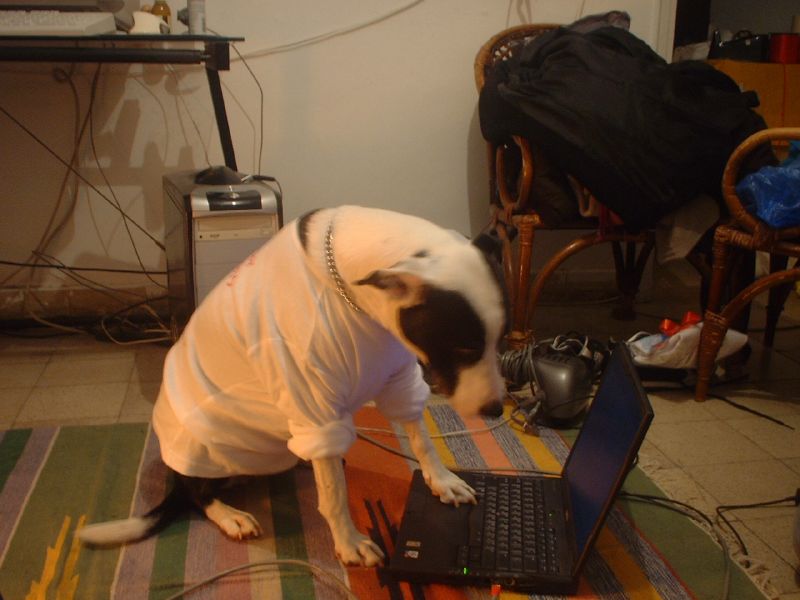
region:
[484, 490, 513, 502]
key on the keyboard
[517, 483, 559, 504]
key on the keyboard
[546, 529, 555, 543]
key on the keyboard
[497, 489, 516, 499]
key on the keyboard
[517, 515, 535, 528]
key on the keyboard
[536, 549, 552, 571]
key on the keyboard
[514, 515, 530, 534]
key on the keyboard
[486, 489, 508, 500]
key on the keyboard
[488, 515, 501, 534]
key on the keyboard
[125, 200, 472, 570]
white and brown dog in a shirt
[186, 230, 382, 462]
white shirt on small dog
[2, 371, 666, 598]
multi colored carpet under dog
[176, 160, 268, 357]
silver and black computer tower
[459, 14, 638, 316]
brown wicker chair by wall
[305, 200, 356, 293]
steel collar on dog's neck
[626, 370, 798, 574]
tan colored tile on ground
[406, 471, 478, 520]
paw of dog on keyboard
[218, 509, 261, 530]
paw of the dog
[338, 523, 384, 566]
paw of the dog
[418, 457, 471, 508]
paw of the dog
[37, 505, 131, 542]
tail of the dog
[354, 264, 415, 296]
ear of the dog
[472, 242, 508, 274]
ear of the dog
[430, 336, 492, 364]
eye of the dog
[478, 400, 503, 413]
nose of the dog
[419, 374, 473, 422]
mouth of the dog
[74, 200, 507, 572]
the dog is wearing a shirt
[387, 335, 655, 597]
the laptop is opened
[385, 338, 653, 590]
the laptop is black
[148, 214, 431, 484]
the shirt is white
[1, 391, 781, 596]
the area rug is multi colored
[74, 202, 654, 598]
the dog is touching the laptop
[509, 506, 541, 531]
a button on the keyboard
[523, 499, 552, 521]
a button on the keyboard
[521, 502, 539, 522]
a button on the keyboard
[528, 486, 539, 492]
a button on the keyboard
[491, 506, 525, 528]
a button on the keyboard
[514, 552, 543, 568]
a button on the keyboard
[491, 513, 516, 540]
a button on the keyboard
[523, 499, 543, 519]
a button on the keyboard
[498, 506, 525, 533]
a button on the keyboard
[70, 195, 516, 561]
dog wearing a white shirt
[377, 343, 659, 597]
an open black laptop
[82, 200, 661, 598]
a dog looking at a laptop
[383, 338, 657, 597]
dog paw on a laptop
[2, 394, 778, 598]
area rug with green, gray and orange stripes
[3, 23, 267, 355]
black cords of a computer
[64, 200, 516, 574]
white shirt on a dog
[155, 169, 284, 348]
computer case on the floor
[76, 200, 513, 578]
black and white dog wearing white tee shirt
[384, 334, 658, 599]
Dell laptop underneath dog's left front paw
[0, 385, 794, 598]
large colorful rug over floor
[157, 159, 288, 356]
computer hard drive sitting on floor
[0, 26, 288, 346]
whole bunch of computer wires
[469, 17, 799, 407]
two wicker-style chairs covered in miscellaneous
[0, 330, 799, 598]
cream-colored tiles covering floor